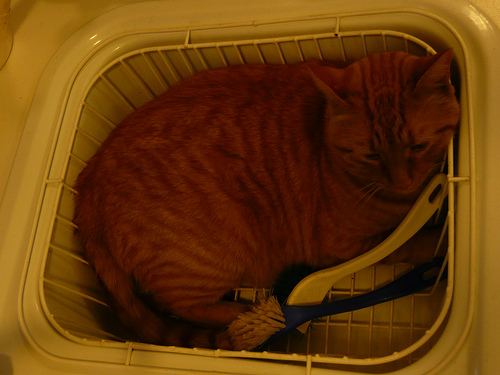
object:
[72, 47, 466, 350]
cat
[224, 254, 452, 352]
scrub brush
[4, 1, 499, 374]
sink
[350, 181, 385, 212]
whisker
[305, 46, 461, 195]
head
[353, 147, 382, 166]
eye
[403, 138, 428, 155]
eye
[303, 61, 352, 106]
ear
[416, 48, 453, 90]
ear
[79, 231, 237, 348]
tail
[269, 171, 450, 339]
scrub brush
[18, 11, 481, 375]
wire basket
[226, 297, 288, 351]
bristles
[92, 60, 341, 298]
body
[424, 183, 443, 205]
opening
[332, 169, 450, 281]
handle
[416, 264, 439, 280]
opening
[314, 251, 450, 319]
handle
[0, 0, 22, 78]
jar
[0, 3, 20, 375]
shelf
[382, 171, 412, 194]
nose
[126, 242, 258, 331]
hind leg